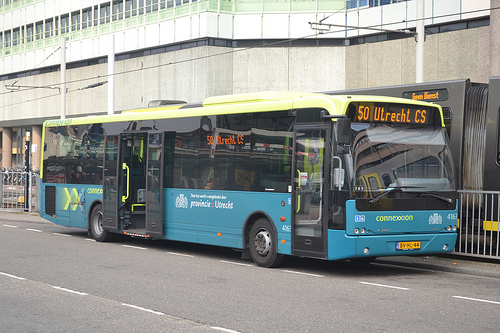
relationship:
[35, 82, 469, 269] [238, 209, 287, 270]
bus has wheel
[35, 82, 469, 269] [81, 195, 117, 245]
bus has wheel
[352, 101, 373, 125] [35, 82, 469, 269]
number on bus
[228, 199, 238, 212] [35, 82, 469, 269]
letter on bus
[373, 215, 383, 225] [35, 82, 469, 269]
letter on bus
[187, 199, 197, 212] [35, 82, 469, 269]
letter on bus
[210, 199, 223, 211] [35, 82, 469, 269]
letter on bus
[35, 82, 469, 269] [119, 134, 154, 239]
bus has door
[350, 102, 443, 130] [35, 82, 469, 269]
electric sign on bus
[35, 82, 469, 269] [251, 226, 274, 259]
bus has rim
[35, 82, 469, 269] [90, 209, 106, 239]
bus has rim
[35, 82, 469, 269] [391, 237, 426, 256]
bus has license plate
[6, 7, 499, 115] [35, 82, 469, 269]
electric wires above bus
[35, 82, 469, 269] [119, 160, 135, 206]
bus has handle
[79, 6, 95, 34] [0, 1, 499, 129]
window on building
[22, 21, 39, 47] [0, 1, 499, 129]
window on building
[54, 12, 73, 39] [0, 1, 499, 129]
window on building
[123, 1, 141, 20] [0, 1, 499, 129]
window on building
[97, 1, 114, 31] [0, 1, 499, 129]
window on building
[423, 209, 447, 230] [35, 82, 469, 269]
logo on bus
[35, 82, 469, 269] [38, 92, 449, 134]
bus has roof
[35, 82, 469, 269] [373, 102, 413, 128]
bus heading for utrecht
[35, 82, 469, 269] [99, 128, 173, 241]
bus has rear doors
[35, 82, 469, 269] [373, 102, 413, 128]
bus going to utrecht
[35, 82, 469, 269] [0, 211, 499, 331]
bus on street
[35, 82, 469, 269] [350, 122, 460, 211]
bus has front window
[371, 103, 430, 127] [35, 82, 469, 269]
route on bus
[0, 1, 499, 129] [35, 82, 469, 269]
building behind bus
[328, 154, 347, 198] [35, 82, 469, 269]
mirror on bus